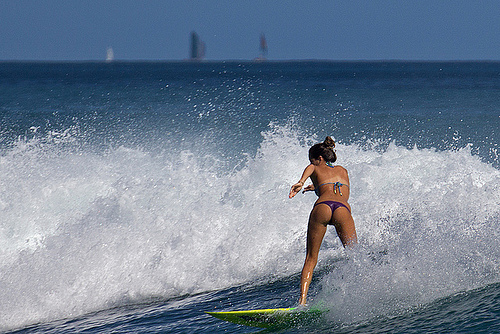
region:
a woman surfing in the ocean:
[200, 118, 390, 330]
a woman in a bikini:
[290, 132, 374, 292]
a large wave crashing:
[16, 132, 243, 297]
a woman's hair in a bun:
[300, 127, 347, 166]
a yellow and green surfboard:
[189, 294, 351, 329]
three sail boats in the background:
[88, 14, 280, 77]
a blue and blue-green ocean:
[1, 57, 496, 168]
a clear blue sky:
[1, 0, 496, 54]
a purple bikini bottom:
[312, 192, 355, 228]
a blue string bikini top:
[306, 157, 361, 194]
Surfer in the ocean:
[206, 143, 468, 327]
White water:
[87, 101, 340, 269]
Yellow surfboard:
[155, 273, 317, 329]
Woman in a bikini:
[296, 163, 396, 236]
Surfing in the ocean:
[141, 94, 353, 313]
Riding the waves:
[81, 118, 451, 311]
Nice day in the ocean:
[91, 76, 388, 314]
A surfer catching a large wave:
[127, 111, 358, 310]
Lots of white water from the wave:
[102, 104, 457, 332]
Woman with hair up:
[265, 134, 352, 176]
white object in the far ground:
[86, 41, 133, 98]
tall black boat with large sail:
[168, 21, 218, 74]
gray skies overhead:
[18, 9, 84, 41]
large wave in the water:
[43, 126, 218, 261]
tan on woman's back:
[323, 173, 350, 187]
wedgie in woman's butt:
[302, 194, 368, 230]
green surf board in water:
[201, 286, 346, 323]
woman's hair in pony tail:
[305, 124, 347, 159]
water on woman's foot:
[272, 246, 337, 303]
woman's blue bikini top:
[309, 179, 384, 207]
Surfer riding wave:
[275, 103, 379, 323]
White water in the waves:
[153, 128, 268, 300]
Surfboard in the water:
[191, 296, 280, 328]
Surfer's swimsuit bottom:
[308, 204, 358, 220]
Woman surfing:
[236, 135, 424, 324]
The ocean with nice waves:
[186, 79, 227, 110]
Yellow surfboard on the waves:
[202, 273, 251, 328]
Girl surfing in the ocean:
[271, 121, 401, 296]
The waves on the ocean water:
[144, 116, 455, 289]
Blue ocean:
[98, 57, 343, 182]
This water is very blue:
[42, 64, 183, 163]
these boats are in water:
[62, 7, 360, 126]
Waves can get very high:
[17, 155, 170, 259]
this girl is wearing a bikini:
[249, 125, 415, 284]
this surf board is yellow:
[194, 290, 336, 332]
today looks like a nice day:
[10, 4, 498, 240]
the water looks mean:
[25, 19, 407, 280]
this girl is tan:
[216, 50, 388, 297]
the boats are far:
[24, 15, 494, 99]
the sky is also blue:
[25, 4, 384, 327]